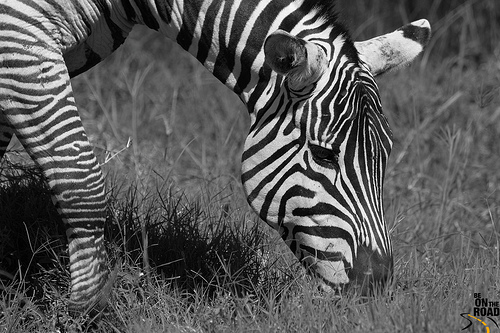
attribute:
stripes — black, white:
[250, 139, 334, 235]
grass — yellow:
[94, 133, 132, 162]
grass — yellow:
[413, 7, 484, 66]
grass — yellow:
[239, 225, 291, 290]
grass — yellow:
[118, 268, 148, 302]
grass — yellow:
[16, 250, 55, 296]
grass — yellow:
[96, 40, 194, 89]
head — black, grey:
[234, 17, 436, 298]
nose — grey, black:
[332, 237, 397, 291]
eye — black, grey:
[306, 140, 349, 174]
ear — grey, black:
[258, 26, 326, 89]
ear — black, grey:
[351, 15, 435, 75]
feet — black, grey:
[73, 284, 108, 330]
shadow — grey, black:
[133, 203, 270, 293]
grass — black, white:
[424, 171, 480, 256]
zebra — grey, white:
[212, 38, 425, 304]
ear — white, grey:
[263, 26, 328, 93]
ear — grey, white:
[368, 19, 438, 75]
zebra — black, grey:
[183, 0, 414, 290]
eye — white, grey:
[305, 132, 338, 173]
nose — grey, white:
[343, 244, 387, 287]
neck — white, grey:
[206, 26, 266, 92]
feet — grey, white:
[52, 254, 112, 312]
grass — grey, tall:
[168, 210, 262, 305]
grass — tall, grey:
[424, 117, 480, 247]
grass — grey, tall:
[419, 127, 473, 227]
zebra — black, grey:
[234, 18, 408, 291]